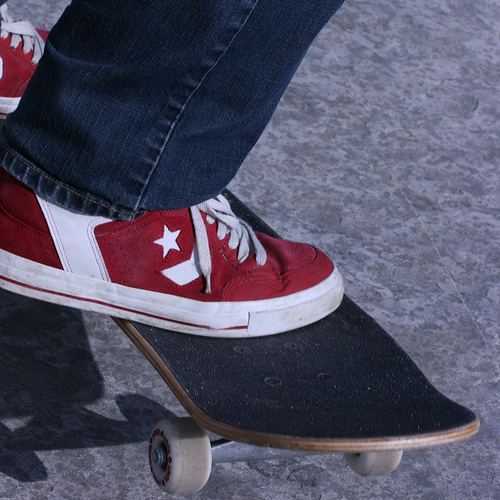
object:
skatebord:
[108, 185, 479, 493]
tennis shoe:
[0, 166, 345, 338]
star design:
[152, 223, 181, 259]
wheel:
[342, 448, 403, 476]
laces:
[188, 193, 266, 293]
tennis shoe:
[0, 1, 50, 116]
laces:
[0, 3, 45, 65]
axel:
[210, 436, 359, 463]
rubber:
[0, 247, 345, 338]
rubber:
[0, 95, 22, 114]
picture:
[0, 1, 499, 498]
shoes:
[0, 153, 345, 338]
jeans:
[0, 0, 345, 222]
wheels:
[148, 415, 213, 493]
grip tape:
[108, 186, 480, 451]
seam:
[118, 0, 259, 222]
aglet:
[203, 271, 211, 293]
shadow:
[0, 286, 178, 481]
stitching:
[0, 136, 138, 221]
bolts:
[261, 373, 282, 387]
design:
[146, 425, 173, 489]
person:
[0, 0, 344, 337]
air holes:
[109, 239, 136, 286]